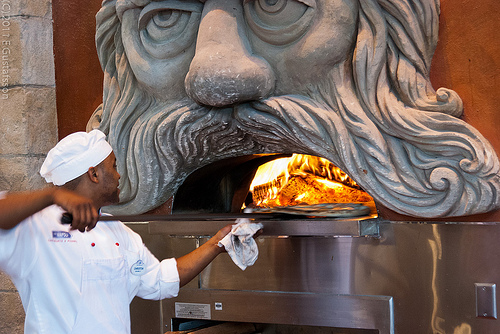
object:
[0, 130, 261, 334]
man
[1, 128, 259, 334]
chef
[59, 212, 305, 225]
long stick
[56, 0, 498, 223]
brick oven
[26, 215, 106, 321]
uniform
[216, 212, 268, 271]
white rag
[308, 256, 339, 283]
steel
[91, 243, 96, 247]
button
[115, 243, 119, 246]
button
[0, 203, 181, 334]
uniform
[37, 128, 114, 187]
chef hat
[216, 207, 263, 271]
rag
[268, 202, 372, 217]
pizza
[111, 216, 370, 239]
pan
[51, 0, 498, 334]
oven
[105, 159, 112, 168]
skin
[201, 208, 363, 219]
stick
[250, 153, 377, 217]
fire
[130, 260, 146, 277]
tag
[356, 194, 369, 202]
pit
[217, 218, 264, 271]
napkin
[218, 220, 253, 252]
hand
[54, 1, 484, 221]
wall